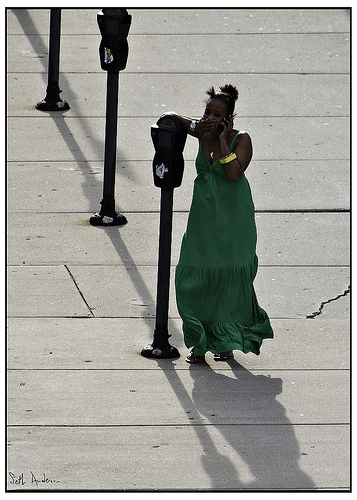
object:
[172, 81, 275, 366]
woman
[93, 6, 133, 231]
meter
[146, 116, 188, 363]
meter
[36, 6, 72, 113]
pole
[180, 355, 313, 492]
shadow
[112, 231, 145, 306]
shadow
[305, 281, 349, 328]
crack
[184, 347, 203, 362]
flip flop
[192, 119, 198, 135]
wrist watch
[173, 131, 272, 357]
dress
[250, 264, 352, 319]
tile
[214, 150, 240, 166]
bracelet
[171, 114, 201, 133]
arm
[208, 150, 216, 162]
necklace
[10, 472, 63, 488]
signature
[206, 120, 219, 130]
mouth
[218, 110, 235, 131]
cellphone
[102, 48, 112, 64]
label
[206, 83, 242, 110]
hair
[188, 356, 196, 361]
toes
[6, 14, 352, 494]
ground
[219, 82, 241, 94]
bun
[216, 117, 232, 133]
cell phone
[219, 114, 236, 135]
hand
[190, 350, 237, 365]
sandals